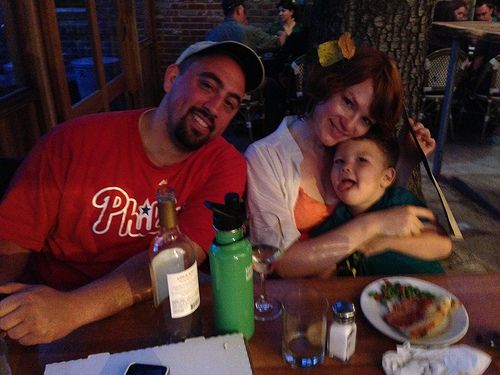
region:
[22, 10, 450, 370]
A small family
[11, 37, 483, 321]
A man, woman and child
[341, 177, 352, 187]
The child's tongue is out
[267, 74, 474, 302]
the woman is hugging the child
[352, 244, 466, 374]
Food on the table.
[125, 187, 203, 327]
an empty wine bottle.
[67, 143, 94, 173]
the man's shirt is red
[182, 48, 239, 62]
The man wears a hat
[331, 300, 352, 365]
A salt dispenser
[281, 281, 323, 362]
an empty glass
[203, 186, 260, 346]
green metal water bottle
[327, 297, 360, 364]
clear glass salt shaker with silver metal lid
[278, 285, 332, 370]
clear drinking glass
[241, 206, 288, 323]
clear wine glass with white wine in it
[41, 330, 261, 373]
white cardboard pizza box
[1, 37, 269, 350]
man wearing baseball cap and red baseball tee shirt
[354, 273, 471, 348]
circular white plate with food on it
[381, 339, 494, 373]
white used paper napkin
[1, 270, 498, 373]
brown wooden table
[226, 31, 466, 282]
woman and child sitting at restaurant table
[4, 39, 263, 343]
a man sitting at table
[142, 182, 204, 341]
an empty liquor bottle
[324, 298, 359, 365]
a glass salt shaker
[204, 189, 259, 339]
a green beverage bottle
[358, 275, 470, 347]
a white plate of food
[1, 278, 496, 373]
a brown dining table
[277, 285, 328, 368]
a clear drinking glass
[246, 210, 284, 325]
a long stemmed glass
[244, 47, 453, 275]
a woman sitting with child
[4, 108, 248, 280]
a men's red t-shirt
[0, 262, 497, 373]
A brown wooden table.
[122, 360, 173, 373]
A cellphone.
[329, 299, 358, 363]
A salt shaker.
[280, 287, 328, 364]
A small glass cup.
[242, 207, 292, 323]
A wine glass.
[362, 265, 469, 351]
A round white plate.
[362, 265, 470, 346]
A plate of food.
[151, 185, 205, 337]
A glass bottle with a white label.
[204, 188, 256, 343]
A green water thermos with a black lid.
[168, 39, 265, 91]
A beige colored ball cap.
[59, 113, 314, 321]
the shirt is red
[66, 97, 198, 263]
the shirt is red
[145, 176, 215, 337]
the bottle is empty